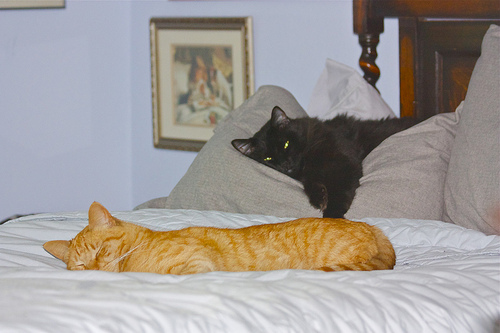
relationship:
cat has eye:
[42, 202, 395, 274] [95, 246, 103, 256]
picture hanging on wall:
[149, 17, 254, 154] [128, 2, 400, 208]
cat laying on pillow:
[231, 105, 424, 217] [168, 84, 460, 222]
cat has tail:
[42, 202, 395, 274] [319, 223, 396, 271]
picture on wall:
[149, 17, 254, 154] [128, 2, 400, 208]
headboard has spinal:
[352, 1, 498, 117] [358, 31, 380, 95]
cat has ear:
[42, 202, 395, 274] [87, 203, 113, 225]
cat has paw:
[231, 105, 424, 217] [311, 184, 329, 210]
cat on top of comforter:
[42, 202, 395, 274] [1, 209, 499, 332]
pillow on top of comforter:
[168, 84, 460, 222] [1, 209, 499, 332]